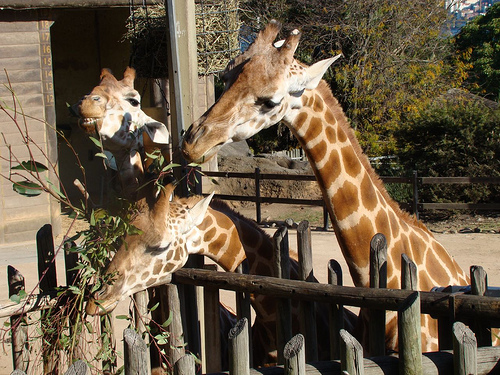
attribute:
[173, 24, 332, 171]
giraffe — brown, spotted, tall, eating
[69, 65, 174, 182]
giraffe — brown, eating, grinning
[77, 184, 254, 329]
giraffe — brown, spotted, short, eating, small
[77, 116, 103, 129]
teeth — white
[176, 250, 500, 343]
fence — wooden, cut wooden pole, pole, wood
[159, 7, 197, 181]
frame — door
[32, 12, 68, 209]
frame — door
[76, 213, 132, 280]
leaves — green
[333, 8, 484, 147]
leaves — tree, yellow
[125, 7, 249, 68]
hay — in background, for feeding, in cage, high up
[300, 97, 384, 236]
spots — brown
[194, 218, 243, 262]
spots — brown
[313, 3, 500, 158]
trees — green, brown, in distance, yellow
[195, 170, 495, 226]
fence — in background, wood, wooden, small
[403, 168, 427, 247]
gate — metal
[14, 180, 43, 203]
leaf — green, small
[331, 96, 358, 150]
comb — brown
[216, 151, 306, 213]
dirt — on side of door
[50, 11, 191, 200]
door — wooden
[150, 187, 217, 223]
ears — white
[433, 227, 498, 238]
stumps — gray, small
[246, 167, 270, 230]
posts — black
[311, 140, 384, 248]
design — brown, tan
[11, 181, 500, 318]
pen — giraffe